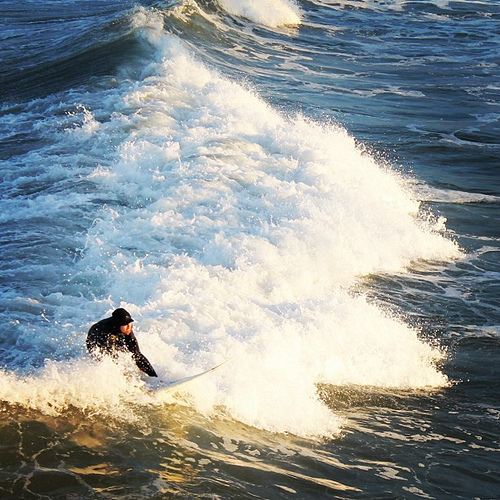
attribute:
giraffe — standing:
[61, 65, 97, 85]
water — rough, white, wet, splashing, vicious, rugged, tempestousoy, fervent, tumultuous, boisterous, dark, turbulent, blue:
[360, 53, 476, 93]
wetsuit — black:
[89, 330, 95, 342]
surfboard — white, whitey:
[172, 367, 207, 388]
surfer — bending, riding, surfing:
[71, 305, 153, 378]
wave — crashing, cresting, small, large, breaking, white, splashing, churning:
[157, 78, 200, 115]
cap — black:
[115, 310, 127, 322]